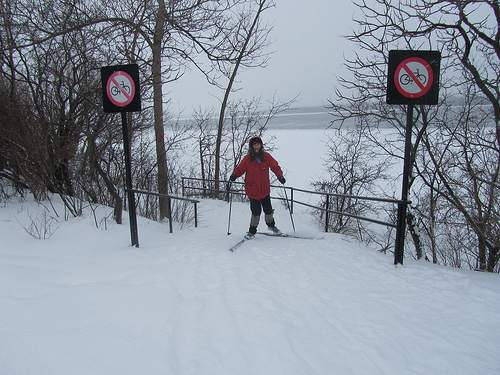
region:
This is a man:
[176, 130, 300, 230]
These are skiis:
[205, 216, 333, 258]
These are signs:
[80, 45, 489, 339]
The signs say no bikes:
[80, 15, 237, 261]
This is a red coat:
[224, 139, 326, 224]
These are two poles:
[187, 176, 279, 236]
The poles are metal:
[215, 163, 392, 277]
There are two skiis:
[172, 147, 402, 364]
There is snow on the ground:
[154, 299, 314, 374]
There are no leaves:
[339, 177, 469, 246]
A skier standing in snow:
[190, 125, 336, 295]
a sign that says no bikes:
[378, 43, 448, 289]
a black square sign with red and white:
[380, 45, 449, 117]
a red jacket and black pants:
[218, 125, 298, 240]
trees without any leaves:
[4, 3, 269, 215]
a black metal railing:
[183, 170, 405, 272]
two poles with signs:
[93, 43, 464, 290]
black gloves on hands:
[223, 171, 295, 190]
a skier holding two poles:
[186, 125, 317, 272]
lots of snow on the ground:
[3, 183, 498, 367]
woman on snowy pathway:
[138, 38, 399, 325]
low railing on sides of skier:
[132, 132, 402, 252]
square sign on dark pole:
[377, 40, 439, 265]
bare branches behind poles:
[5, 1, 495, 256]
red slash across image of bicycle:
[385, 50, 437, 105]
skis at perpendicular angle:
[220, 211, 325, 256]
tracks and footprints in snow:
[17, 215, 482, 365]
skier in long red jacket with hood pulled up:
[225, 131, 285, 206]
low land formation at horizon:
[155, 100, 495, 131]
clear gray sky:
[5, 1, 495, 98]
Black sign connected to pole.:
[83, 46, 184, 146]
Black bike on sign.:
[105, 65, 135, 125]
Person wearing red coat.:
[234, 130, 286, 220]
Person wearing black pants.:
[245, 197, 289, 251]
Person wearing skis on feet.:
[226, 219, 343, 256]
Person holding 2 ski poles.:
[202, 170, 329, 235]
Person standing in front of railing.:
[204, 155, 366, 299]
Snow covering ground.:
[93, 268, 318, 368]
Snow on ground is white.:
[74, 275, 224, 335]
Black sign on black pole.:
[383, 58, 453, 163]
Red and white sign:
[378, 44, 454, 117]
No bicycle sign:
[381, 39, 456, 121]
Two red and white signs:
[70, 43, 458, 132]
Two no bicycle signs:
[77, 43, 463, 121]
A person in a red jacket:
[216, 120, 328, 270]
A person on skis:
[215, 129, 320, 271]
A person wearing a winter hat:
[241, 124, 271, 170]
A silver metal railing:
[318, 183, 384, 239]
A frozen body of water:
[300, 110, 330, 147]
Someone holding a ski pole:
[220, 172, 245, 250]